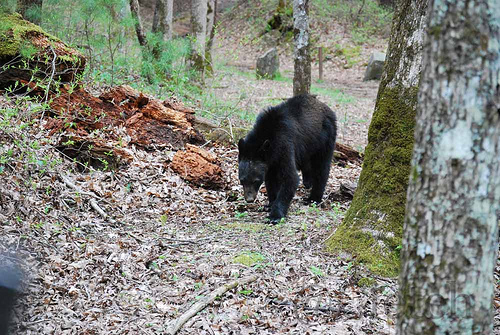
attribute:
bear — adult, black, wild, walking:
[224, 90, 339, 226]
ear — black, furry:
[259, 140, 276, 154]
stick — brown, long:
[159, 262, 265, 334]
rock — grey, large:
[365, 50, 379, 79]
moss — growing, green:
[366, 70, 402, 241]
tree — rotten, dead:
[9, 15, 170, 152]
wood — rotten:
[176, 145, 221, 185]